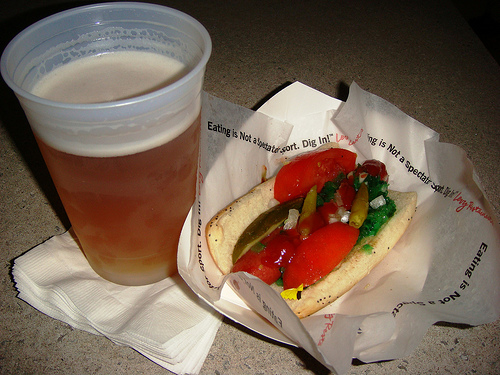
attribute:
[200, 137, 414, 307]
hotdog — spicy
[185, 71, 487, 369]
tissue — white, paper, wax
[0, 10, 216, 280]
drink — cool, brown, white, plastic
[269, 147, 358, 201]
tomato — red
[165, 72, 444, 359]
box — white, cardboard, paper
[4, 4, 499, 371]
table — grey, brown, mottled, granite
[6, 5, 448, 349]
things — kept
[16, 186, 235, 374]
tissue — under, paper, stacked, white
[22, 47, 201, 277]
beer — hazelnut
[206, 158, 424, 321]
bun — poppyseed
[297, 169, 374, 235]
peppers — hot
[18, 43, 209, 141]
foam — white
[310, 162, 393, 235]
relish — green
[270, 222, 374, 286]
pepper — red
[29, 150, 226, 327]
napkins — white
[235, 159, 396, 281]
toppings — red, green